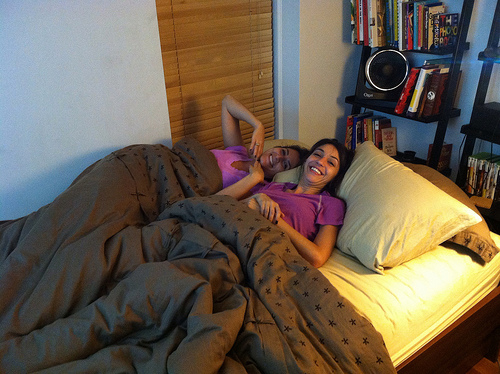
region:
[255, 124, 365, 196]
they are laying down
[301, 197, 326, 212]
the shirt is purple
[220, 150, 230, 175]
the shirt is pink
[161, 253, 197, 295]
the blanket is brown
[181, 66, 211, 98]
the blind is closed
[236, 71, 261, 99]
the blind is brown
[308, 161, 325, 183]
the lady is smiling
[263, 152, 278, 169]
the girl is smiling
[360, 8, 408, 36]
the books are standing up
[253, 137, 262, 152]
she is wearing a ring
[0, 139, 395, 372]
a dark brown comforter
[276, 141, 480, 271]
a large bed pillow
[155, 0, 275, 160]
brown wood venetian blinds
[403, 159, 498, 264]
a large brown pillow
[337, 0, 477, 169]
a black wood bookcase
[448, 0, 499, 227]
a black wood bookcase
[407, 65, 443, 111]
a white book on shelf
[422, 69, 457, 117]
a brown book on shelf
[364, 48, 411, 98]
a black and silver fan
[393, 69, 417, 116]
a red book spine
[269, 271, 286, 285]
The symbol is black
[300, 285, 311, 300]
The symbol is black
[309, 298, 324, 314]
The symbol is black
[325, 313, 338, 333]
The symbol is black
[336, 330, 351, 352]
The symbol is black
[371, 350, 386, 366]
The symbol is black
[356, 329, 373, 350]
The symbol is black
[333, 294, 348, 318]
The symbol is black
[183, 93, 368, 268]
two women in a bed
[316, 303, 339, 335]
star on the comforter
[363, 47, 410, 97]
fan on the shelf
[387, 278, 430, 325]
white sheets on the bed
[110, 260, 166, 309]
creases on the comforter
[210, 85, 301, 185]
girl wearing a pink shirt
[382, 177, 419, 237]
white pillow on the bed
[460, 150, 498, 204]
games on the shelf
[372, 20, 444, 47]
books on the shelf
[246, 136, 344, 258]
a woman lying in bed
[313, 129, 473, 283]
a large grey pillow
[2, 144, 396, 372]
a brown thick comforter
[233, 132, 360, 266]
woman with hands crossed in bed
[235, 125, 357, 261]
woman with hands crossed in bed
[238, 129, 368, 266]
woman with hands crossed in bed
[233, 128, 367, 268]
woman with hands crossed in bed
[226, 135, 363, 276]
woman with hands crossed in bed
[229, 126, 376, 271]
woman with hands crossed in bed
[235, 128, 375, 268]
woman with hands crossed in bed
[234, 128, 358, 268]
woman with hands crossed in bed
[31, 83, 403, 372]
Both girls are covered up by the blanket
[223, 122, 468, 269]
Girls are sleeping on multiple pillows in the bed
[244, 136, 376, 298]
Girl near the open edge of the bed is crossing her arms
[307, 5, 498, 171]
Bookshelf above the bed is full of media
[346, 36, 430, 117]
Circular object sits above the girls on the shelf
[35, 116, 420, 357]
Brown blanket has different designs on the blanket sides